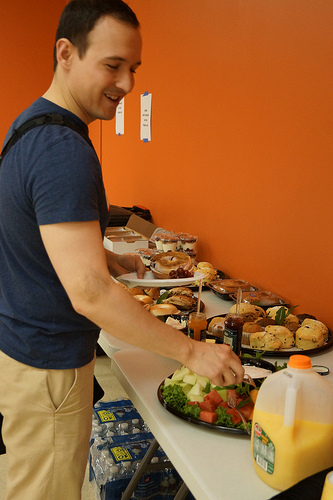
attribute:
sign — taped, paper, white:
[135, 89, 157, 149]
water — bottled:
[82, 397, 167, 500]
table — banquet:
[104, 219, 332, 499]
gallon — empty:
[248, 349, 331, 495]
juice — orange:
[252, 411, 330, 488]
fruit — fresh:
[185, 387, 251, 423]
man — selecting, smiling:
[3, 0, 244, 499]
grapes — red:
[169, 267, 196, 280]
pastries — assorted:
[220, 302, 325, 349]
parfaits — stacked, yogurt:
[133, 233, 201, 260]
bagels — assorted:
[129, 286, 195, 315]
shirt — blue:
[1, 95, 112, 368]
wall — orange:
[104, 5, 331, 331]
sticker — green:
[250, 423, 276, 475]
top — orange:
[287, 353, 314, 374]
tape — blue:
[141, 138, 149, 143]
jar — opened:
[222, 314, 250, 355]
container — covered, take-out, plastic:
[230, 284, 293, 310]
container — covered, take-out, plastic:
[201, 277, 260, 302]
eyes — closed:
[105, 61, 140, 75]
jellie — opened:
[185, 315, 210, 342]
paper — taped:
[113, 96, 125, 132]